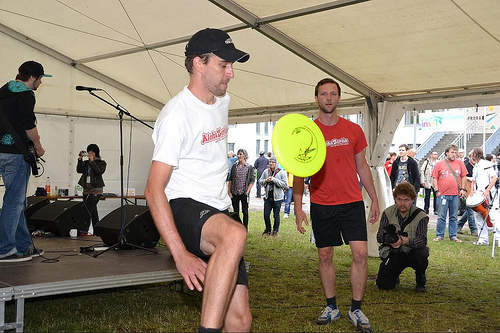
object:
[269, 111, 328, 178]
frisbee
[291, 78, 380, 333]
man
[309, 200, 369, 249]
shorts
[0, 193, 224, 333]
stage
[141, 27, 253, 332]
men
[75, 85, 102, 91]
microphone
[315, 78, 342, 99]
hair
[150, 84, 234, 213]
shirt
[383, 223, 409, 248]
camera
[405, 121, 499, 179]
stairs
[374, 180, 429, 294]
person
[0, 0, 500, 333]
picture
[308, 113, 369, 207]
tshirt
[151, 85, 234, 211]
white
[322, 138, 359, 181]
red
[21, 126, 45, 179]
instrument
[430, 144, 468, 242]
people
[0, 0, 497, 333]
tent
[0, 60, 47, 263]
guy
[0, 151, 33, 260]
jeans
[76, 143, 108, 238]
woman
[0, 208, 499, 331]
grass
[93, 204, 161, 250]
speakers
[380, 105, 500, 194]
building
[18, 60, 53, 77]
hat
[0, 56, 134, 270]
band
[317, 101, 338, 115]
beard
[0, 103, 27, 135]
black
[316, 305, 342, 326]
shoes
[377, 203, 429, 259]
vest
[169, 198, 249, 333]
legs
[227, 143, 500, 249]
crowd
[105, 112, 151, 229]
stand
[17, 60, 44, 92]
head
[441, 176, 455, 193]
orange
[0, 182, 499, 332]
ground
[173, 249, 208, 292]
hand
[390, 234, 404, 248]
hands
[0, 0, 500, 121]
roof